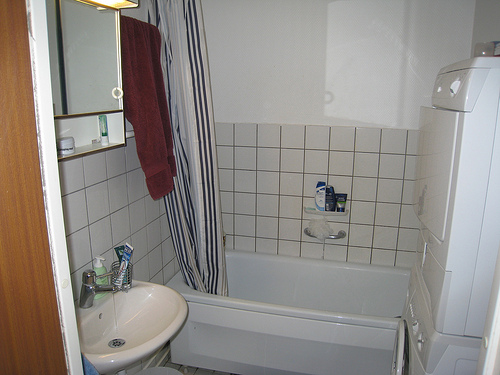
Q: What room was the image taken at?
A: It was taken at the bathroom.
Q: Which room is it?
A: It is a bathroom.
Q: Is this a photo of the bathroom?
A: Yes, it is showing the bathroom.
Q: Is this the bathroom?
A: Yes, it is the bathroom.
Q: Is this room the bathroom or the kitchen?
A: It is the bathroom.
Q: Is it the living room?
A: No, it is the bathroom.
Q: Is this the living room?
A: No, it is the bathroom.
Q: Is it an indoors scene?
A: Yes, it is indoors.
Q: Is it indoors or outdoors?
A: It is indoors.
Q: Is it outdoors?
A: No, it is indoors.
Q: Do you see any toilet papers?
A: No, there are no toilet papers.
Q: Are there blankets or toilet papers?
A: No, there are no toilet papers or blankets.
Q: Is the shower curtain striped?
A: Yes, the shower curtain is striped.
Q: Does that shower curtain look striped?
A: Yes, the shower curtain is striped.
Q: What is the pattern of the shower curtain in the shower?
A: The shower curtain is striped.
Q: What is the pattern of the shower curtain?
A: The shower curtain is striped.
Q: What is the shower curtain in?
A: The shower curtain is in the shower.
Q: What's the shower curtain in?
A: The shower curtain is in the shower.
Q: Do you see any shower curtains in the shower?
A: Yes, there is a shower curtain in the shower.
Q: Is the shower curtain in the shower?
A: Yes, the shower curtain is in the shower.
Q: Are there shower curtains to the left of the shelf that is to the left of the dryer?
A: Yes, there is a shower curtain to the left of the shelf.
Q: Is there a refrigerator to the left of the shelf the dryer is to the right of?
A: No, there is a shower curtain to the left of the shelf.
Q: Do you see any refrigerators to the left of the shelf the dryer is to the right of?
A: No, there is a shower curtain to the left of the shelf.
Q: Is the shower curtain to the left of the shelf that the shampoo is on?
A: Yes, the shower curtain is to the left of the shelf.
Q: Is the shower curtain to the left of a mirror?
A: No, the shower curtain is to the left of the shelf.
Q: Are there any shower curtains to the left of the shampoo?
A: Yes, there is a shower curtain to the left of the shampoo.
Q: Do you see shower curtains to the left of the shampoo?
A: Yes, there is a shower curtain to the left of the shampoo.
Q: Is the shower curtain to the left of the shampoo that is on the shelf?
A: Yes, the shower curtain is to the left of the shampoo.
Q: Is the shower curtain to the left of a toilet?
A: No, the shower curtain is to the left of the shampoo.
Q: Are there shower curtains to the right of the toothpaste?
A: Yes, there is a shower curtain to the right of the toothpaste.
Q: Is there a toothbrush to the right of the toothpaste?
A: No, there is a shower curtain to the right of the toothpaste.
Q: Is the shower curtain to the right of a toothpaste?
A: Yes, the shower curtain is to the right of a toothpaste.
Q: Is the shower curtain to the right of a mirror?
A: No, the shower curtain is to the right of a toothpaste.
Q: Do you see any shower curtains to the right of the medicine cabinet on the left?
A: Yes, there is a shower curtain to the right of the medicine cabinet.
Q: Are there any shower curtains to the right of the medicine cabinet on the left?
A: Yes, there is a shower curtain to the right of the medicine cabinet.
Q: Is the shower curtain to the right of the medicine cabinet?
A: Yes, the shower curtain is to the right of the medicine cabinet.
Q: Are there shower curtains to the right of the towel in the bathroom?
A: Yes, there is a shower curtain to the right of the towel.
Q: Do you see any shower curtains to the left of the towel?
A: No, the shower curtain is to the right of the towel.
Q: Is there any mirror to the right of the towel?
A: No, there is a shower curtain to the right of the towel.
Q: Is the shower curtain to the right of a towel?
A: Yes, the shower curtain is to the right of a towel.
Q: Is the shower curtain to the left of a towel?
A: No, the shower curtain is to the right of a towel.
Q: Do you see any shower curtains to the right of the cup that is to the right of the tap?
A: Yes, there is a shower curtain to the right of the cup.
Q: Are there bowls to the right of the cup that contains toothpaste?
A: No, there is a shower curtain to the right of the cup.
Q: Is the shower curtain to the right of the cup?
A: Yes, the shower curtain is to the right of the cup.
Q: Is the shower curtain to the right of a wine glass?
A: No, the shower curtain is to the right of the cup.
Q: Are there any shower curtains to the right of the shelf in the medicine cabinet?
A: Yes, there is a shower curtain to the right of the shelf.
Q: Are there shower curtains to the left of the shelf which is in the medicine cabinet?
A: No, the shower curtain is to the right of the shelf.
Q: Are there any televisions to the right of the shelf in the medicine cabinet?
A: No, there is a shower curtain to the right of the shelf.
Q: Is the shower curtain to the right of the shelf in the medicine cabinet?
A: Yes, the shower curtain is to the right of the shelf.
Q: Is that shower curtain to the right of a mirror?
A: No, the shower curtain is to the right of the shelf.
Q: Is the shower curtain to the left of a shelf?
A: No, the shower curtain is to the right of a shelf.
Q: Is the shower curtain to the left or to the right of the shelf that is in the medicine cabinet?
A: The shower curtain is to the right of the shelf.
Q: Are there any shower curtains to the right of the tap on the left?
A: Yes, there is a shower curtain to the right of the faucet.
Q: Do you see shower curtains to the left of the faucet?
A: No, the shower curtain is to the right of the faucet.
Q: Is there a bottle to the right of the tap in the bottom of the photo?
A: No, there is a shower curtain to the right of the tap.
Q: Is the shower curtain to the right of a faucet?
A: Yes, the shower curtain is to the right of a faucet.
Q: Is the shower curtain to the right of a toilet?
A: No, the shower curtain is to the right of a faucet.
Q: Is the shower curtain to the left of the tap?
A: No, the shower curtain is to the right of the tap.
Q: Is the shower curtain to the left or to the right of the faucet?
A: The shower curtain is to the right of the faucet.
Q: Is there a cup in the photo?
A: Yes, there is a cup.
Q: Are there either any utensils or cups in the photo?
A: Yes, there is a cup.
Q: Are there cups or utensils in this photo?
A: Yes, there is a cup.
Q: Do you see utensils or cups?
A: Yes, there is a cup.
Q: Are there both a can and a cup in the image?
A: No, there is a cup but no cans.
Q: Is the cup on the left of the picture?
A: Yes, the cup is on the left of the image.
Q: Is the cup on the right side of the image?
A: No, the cup is on the left of the image.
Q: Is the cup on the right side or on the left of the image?
A: The cup is on the left of the image.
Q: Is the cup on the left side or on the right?
A: The cup is on the left of the image.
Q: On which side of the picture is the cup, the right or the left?
A: The cup is on the left of the image.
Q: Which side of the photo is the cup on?
A: The cup is on the left of the image.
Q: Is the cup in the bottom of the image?
A: Yes, the cup is in the bottom of the image.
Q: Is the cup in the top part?
A: No, the cup is in the bottom of the image.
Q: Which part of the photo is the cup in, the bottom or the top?
A: The cup is in the bottom of the image.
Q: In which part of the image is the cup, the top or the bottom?
A: The cup is in the bottom of the image.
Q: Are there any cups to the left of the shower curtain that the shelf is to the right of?
A: Yes, there is a cup to the left of the shower curtain.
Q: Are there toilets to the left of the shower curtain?
A: No, there is a cup to the left of the shower curtain.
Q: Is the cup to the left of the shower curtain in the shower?
A: Yes, the cup is to the left of the shower curtain.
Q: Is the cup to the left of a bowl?
A: No, the cup is to the left of the shower curtain.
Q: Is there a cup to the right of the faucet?
A: Yes, there is a cup to the right of the faucet.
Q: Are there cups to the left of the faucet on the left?
A: No, the cup is to the right of the faucet.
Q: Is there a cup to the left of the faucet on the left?
A: No, the cup is to the right of the faucet.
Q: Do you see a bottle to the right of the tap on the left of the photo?
A: No, there is a cup to the right of the tap.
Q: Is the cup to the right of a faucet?
A: Yes, the cup is to the right of a faucet.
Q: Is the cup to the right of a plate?
A: No, the cup is to the right of a faucet.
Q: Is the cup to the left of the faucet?
A: No, the cup is to the right of the faucet.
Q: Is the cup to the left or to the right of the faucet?
A: The cup is to the right of the faucet.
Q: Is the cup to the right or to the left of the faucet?
A: The cup is to the right of the faucet.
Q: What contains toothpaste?
A: The cup contains toothpaste.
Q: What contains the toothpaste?
A: The cup contains toothpaste.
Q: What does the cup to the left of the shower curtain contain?
A: The cup contains toothpaste.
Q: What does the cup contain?
A: The cup contains toothpaste.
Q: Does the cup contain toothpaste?
A: Yes, the cup contains toothpaste.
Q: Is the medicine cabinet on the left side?
A: Yes, the medicine cabinet is on the left of the image.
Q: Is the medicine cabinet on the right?
A: No, the medicine cabinet is on the left of the image.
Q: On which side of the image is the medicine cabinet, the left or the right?
A: The medicine cabinet is on the left of the image.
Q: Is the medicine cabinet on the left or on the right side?
A: The medicine cabinet is on the left of the image.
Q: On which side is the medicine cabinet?
A: The medicine cabinet is on the left of the image.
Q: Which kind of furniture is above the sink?
A: The piece of furniture is a medicine cabinet.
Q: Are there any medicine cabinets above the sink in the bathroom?
A: Yes, there is a medicine cabinet above the sink.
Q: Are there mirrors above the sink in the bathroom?
A: No, there is a medicine cabinet above the sink.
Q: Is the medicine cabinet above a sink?
A: Yes, the medicine cabinet is above a sink.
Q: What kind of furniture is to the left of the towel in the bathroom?
A: The piece of furniture is a medicine cabinet.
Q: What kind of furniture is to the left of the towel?
A: The piece of furniture is a medicine cabinet.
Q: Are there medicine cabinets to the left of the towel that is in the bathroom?
A: Yes, there is a medicine cabinet to the left of the towel.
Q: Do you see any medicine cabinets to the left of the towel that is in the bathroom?
A: Yes, there is a medicine cabinet to the left of the towel.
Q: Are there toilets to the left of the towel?
A: No, there is a medicine cabinet to the left of the towel.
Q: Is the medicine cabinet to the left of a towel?
A: Yes, the medicine cabinet is to the left of a towel.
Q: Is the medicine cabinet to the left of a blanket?
A: No, the medicine cabinet is to the left of a towel.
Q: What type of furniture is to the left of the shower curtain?
A: The piece of furniture is a medicine cabinet.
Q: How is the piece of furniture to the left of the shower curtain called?
A: The piece of furniture is a medicine cabinet.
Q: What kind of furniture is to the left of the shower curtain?
A: The piece of furniture is a medicine cabinet.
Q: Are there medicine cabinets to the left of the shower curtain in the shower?
A: Yes, there is a medicine cabinet to the left of the shower curtain.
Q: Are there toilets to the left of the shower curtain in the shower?
A: No, there is a medicine cabinet to the left of the shower curtain.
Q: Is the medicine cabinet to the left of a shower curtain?
A: Yes, the medicine cabinet is to the left of a shower curtain.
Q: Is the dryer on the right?
A: Yes, the dryer is on the right of the image.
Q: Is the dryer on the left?
A: No, the dryer is on the right of the image.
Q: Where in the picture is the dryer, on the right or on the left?
A: The dryer is on the right of the image.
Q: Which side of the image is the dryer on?
A: The dryer is on the right of the image.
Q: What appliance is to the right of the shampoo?
A: The appliance is a dryer.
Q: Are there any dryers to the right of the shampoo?
A: Yes, there is a dryer to the right of the shampoo.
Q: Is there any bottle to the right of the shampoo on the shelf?
A: No, there is a dryer to the right of the shampoo.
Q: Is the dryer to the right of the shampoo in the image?
A: Yes, the dryer is to the right of the shampoo.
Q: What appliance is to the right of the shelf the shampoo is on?
A: The appliance is a dryer.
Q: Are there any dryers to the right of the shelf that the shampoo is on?
A: Yes, there is a dryer to the right of the shelf.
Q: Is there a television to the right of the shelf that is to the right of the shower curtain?
A: No, there is a dryer to the right of the shelf.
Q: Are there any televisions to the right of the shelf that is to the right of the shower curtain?
A: No, there is a dryer to the right of the shelf.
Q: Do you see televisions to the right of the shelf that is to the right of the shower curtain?
A: No, there is a dryer to the right of the shelf.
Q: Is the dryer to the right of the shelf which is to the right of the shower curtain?
A: Yes, the dryer is to the right of the shelf.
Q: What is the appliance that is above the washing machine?
A: The appliance is a dryer.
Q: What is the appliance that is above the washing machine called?
A: The appliance is a dryer.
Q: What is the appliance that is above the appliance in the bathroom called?
A: The appliance is a dryer.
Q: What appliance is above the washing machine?
A: The appliance is a dryer.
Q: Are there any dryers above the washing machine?
A: Yes, there is a dryer above the washing machine.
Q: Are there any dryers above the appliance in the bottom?
A: Yes, there is a dryer above the washing machine.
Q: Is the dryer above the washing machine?
A: Yes, the dryer is above the washing machine.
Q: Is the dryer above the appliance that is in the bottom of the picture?
A: Yes, the dryer is above the washing machine.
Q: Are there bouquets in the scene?
A: No, there are no bouquets.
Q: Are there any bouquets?
A: No, there are no bouquets.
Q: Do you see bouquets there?
A: No, there are no bouquets.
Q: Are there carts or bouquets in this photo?
A: No, there are no bouquets or carts.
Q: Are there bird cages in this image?
A: No, there are no bird cages.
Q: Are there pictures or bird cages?
A: No, there are no bird cages or pictures.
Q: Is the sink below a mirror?
A: No, the sink is below the medicine cabinet.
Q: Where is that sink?
A: The sink is in the bathroom.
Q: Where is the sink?
A: The sink is in the bathroom.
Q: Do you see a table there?
A: No, there are no tables.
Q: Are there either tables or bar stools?
A: No, there are no tables or bar stools.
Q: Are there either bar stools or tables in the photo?
A: No, there are no tables or bar stools.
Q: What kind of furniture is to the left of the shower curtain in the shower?
A: The piece of furniture is a shelf.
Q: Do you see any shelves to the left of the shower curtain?
A: Yes, there is a shelf to the left of the shower curtain.